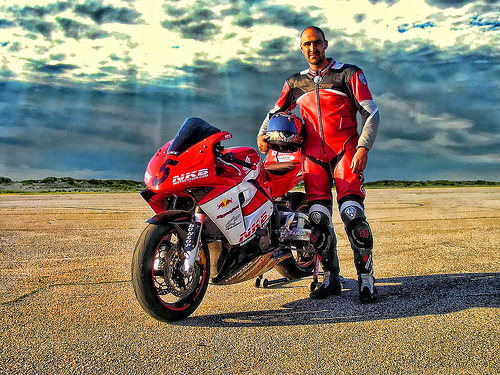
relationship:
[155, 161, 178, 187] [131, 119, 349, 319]
5 on bike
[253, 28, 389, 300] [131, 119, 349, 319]
man next to bike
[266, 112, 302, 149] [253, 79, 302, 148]
helmet under arm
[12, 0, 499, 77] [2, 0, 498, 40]
sun beaming through clouds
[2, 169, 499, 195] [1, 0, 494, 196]
mountains in background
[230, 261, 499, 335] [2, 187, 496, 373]
marks on pavement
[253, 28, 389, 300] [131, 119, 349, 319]
man standing near motorcycle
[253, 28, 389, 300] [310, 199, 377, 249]
man wearing knee pads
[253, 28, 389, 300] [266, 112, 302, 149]
man has helmet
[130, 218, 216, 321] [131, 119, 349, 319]
wheel of motor cycle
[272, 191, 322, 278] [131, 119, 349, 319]
wheel of motor cycle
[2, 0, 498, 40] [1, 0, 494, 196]
clouds in sky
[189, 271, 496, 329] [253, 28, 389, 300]
marks near man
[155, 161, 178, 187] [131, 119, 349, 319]
5 front of motor cycle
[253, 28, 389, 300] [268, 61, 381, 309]
man wearing dirt bike suit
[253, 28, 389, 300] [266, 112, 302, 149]
man holding helmet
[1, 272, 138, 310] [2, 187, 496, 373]
crack in pavement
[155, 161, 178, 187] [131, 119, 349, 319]
5 front of bike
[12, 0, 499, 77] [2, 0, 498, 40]
light poking through clouds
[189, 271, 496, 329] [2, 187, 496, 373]
marks on ground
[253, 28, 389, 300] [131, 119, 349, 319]
man standing near motor cycle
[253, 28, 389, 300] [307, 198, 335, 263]
man wearing knee pad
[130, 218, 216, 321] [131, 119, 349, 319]
tire of motorcycle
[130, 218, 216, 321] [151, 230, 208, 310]
tire has red rim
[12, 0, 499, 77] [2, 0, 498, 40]
sunlight breaking through clouds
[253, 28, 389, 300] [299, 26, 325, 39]
man with short hair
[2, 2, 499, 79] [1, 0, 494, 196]
cloudy in distance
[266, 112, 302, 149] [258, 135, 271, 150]
helmet in hand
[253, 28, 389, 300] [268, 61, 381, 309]
rider wear dirt bike suit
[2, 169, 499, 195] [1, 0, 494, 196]
mountains in distance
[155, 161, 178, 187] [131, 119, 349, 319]
5 showing on bike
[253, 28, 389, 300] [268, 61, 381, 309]
rider wear red